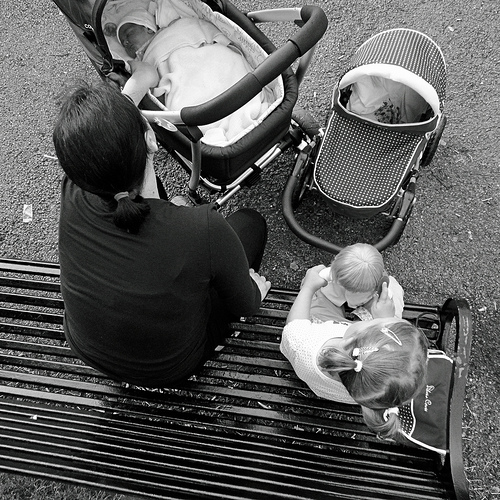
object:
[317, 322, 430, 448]
hair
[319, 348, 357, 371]
pigtail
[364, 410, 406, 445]
pigtail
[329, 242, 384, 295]
hair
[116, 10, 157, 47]
white hat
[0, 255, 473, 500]
bench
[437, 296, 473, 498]
armrest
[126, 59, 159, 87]
hand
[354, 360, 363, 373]
hair band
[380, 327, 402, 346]
barrette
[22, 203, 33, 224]
trash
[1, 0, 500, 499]
ground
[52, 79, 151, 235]
hair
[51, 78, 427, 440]
people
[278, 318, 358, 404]
shirt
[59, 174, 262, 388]
shirt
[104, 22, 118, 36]
pacifier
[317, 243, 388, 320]
doll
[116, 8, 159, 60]
baby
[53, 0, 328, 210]
baby carriage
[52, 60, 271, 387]
girl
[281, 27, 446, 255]
carriage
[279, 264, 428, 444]
girl